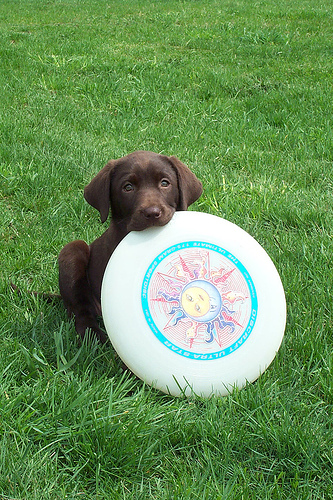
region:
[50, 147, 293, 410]
A brown puppy with a fisbee.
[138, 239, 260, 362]
A sun symbol on a frisbee.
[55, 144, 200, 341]
A young brown puppy.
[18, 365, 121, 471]
The grass is green.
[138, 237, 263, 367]
A blue circle around the sun symbol.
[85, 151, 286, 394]
A frisbee in the puppy's mouth.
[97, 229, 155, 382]
The edge of the frisbee is white.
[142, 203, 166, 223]
The puppy's nose is brown.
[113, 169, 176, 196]
The puppy has brown eyes.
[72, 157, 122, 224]
A brown puppy ears.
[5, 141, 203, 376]
brown puppy lying in grass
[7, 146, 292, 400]
brown puppy in grass holding frisbee in mouth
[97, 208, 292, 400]
white round frisbee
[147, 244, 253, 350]
image of sun in middle of frisbee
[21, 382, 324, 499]
blades of grass in green field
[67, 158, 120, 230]
brown puppy ear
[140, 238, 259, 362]
round blue circle in middle of frisbee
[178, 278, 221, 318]
blue moon in center of frisbee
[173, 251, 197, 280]
red rayon front of frisbee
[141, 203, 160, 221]
brown puppy nose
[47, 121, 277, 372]
Puppy holding a frisbee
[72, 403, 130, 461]
The grass is long and green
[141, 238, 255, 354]
Frisbee has a sun on it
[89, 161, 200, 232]
Frisbee in dogs mouth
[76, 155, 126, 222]
Puppy has floppy ears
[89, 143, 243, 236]
Puppy looks proud of himself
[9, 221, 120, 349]
Puppy is sitting on grass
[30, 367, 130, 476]
The blades of grass are thick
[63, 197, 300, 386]
The frisbee is white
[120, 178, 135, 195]
Puppy has brown eyes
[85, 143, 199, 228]
a brown dog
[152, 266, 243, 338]
logo on the frisbee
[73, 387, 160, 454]
the grass is long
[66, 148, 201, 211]
a dog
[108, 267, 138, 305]
frisbee is white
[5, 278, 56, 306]
the dogs tail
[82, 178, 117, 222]
the dogs ear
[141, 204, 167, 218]
nose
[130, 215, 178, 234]
dog is biting the frisbee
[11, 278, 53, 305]
the tail is in the grass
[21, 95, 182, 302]
the puppy is brown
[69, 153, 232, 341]
the puppy is brown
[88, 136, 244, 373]
puppy biting the frisbee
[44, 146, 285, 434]
puppy biting the frisbee